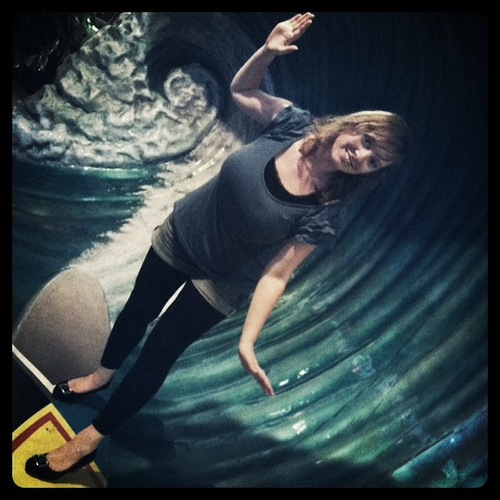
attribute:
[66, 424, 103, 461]
leg — white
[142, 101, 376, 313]
shirt — short sleeved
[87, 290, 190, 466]
pants — black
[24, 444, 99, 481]
heels — black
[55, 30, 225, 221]
water — fake, blue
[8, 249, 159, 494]
surfboard — gray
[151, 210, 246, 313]
grey shorts — gray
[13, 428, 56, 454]
mat — yellow, brown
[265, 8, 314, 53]
hand — raised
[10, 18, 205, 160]
rocks — gray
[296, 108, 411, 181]
hair — blonde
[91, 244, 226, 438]
pants — black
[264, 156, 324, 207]
undershirt — black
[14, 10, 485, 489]
tunnel — dark